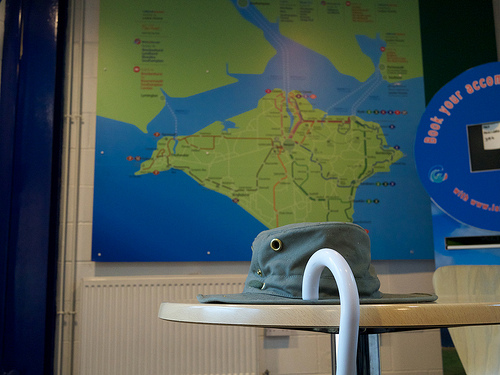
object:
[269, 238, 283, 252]
hole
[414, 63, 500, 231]
advertising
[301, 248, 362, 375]
pole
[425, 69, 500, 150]
writing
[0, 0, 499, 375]
room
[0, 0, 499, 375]
photo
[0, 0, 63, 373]
blue door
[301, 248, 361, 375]
label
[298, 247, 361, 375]
handle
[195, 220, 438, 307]
hat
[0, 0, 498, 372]
wall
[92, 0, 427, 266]
map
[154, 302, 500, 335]
side table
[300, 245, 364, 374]
hook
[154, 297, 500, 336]
table top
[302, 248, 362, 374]
object